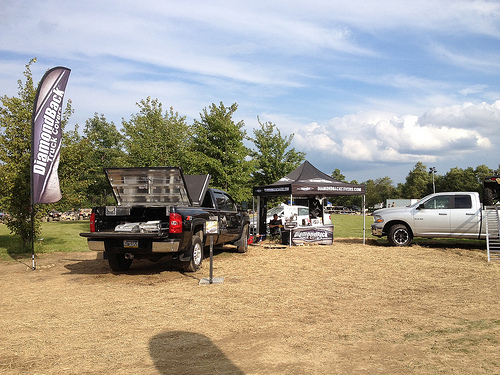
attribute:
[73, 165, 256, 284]
truck — black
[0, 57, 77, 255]
tree — tall, in background, green, in line, on side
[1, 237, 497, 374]
field — grass, brown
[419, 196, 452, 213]
window — of a screen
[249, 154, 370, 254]
tent — black, for people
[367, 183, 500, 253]
truck — silver, white, grey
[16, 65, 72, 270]
banner — on pole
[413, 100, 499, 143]
cloud — white, on side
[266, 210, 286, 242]
person — at the park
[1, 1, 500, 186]
sky — cloudy, blue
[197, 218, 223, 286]
sign — wind sign, black, white